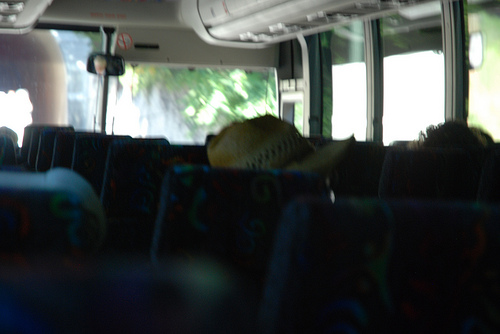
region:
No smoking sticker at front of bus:
[116, 28, 137, 53]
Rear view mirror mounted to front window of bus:
[86, 28, 135, 83]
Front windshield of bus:
[3, 19, 294, 167]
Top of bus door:
[277, 66, 308, 140]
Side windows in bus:
[307, 28, 497, 151]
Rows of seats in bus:
[21, 129, 421, 315]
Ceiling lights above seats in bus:
[2, 1, 27, 26]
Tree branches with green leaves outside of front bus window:
[150, 68, 260, 116]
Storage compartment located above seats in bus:
[185, 1, 294, 34]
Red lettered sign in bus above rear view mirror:
[83, 8, 136, 27]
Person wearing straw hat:
[201, 108, 363, 208]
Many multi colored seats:
[119, 171, 317, 268]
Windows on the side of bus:
[302, 57, 458, 113]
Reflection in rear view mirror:
[79, 30, 146, 90]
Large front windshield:
[3, 30, 217, 119]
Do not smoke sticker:
[114, 30, 149, 66]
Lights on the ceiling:
[4, 3, 36, 33]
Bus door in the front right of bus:
[261, 69, 328, 169]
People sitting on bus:
[376, 93, 497, 234]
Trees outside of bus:
[140, 82, 257, 119]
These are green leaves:
[193, 70, 237, 104]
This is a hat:
[228, 135, 243, 152]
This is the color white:
[397, 71, 430, 108]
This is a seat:
[234, 155, 498, 332]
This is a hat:
[192, 75, 364, 195]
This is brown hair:
[405, 102, 498, 167]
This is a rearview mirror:
[72, 40, 152, 87]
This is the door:
[276, 70, 321, 158]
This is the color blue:
[272, 236, 301, 279]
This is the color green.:
[213, 80, 220, 89]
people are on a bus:
[204, 111, 490, 186]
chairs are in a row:
[16, 120, 479, 311]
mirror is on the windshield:
[87, 52, 126, 79]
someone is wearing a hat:
[207, 115, 352, 176]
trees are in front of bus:
[126, 58, 277, 136]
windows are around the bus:
[2, 0, 499, 143]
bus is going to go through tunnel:
[0, 29, 79, 144]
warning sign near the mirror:
[115, 32, 132, 49]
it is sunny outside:
[5, 27, 499, 142]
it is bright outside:
[4, 31, 281, 153]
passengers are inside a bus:
[1, 0, 497, 316]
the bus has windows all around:
[2, 25, 497, 163]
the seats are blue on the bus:
[0, 123, 482, 321]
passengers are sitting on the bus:
[2, 115, 497, 330]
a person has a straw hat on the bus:
[185, 95, 358, 217]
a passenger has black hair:
[402, 116, 497, 186]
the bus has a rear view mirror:
[77, 20, 132, 87]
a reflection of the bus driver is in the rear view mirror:
[83, 47, 128, 77]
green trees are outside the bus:
[65, 26, 495, 141]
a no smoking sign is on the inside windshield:
[110, 26, 136, 66]